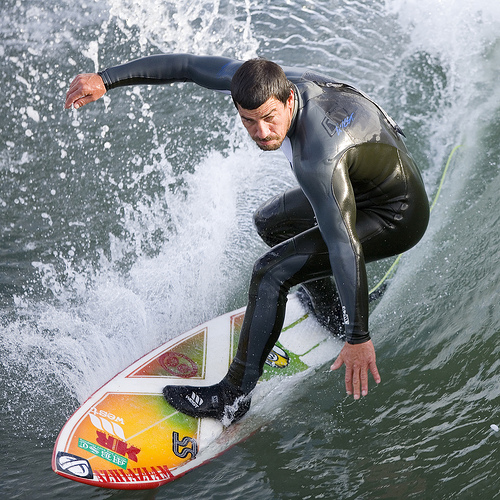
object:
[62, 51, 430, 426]
man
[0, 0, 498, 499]
ocean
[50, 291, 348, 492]
surfboard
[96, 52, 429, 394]
wet suit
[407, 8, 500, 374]
waves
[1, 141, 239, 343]
waves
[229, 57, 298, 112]
dark hair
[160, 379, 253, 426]
shoe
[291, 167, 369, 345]
arms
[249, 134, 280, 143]
mustache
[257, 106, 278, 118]
eyebrows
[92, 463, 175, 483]
wording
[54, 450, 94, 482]
logo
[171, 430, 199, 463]
writing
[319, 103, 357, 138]
writing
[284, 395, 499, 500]
water